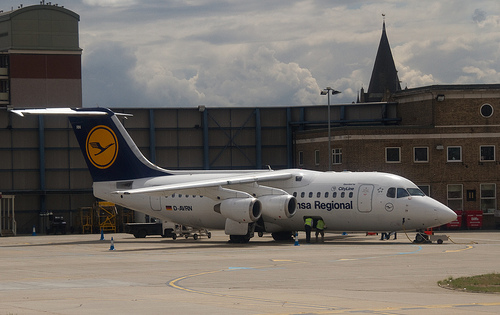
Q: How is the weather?
A: It is cloudy.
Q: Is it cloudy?
A: Yes, it is cloudy.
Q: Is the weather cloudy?
A: Yes, it is cloudy.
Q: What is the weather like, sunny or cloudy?
A: It is cloudy.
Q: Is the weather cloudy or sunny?
A: It is cloudy.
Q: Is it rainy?
A: No, it is cloudy.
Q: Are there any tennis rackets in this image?
A: No, there are no tennis rackets.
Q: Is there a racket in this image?
A: No, there are no rackets.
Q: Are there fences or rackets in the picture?
A: No, there are no rackets or fences.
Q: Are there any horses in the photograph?
A: No, there are no horses.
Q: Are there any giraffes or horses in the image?
A: No, there are no horses or giraffes.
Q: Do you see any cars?
A: No, there are no cars.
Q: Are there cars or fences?
A: No, there are no cars or fences.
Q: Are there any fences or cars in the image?
A: No, there are no cars or fences.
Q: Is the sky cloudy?
A: Yes, the sky is cloudy.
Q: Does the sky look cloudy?
A: Yes, the sky is cloudy.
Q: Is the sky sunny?
A: No, the sky is cloudy.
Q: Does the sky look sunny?
A: No, the sky is cloudy.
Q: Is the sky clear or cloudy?
A: The sky is cloudy.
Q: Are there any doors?
A: Yes, there is a door.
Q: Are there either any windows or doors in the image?
A: Yes, there is a door.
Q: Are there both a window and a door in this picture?
A: Yes, there are both a door and a window.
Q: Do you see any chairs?
A: No, there are no chairs.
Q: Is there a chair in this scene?
A: No, there are no chairs.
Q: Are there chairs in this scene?
A: No, there are no chairs.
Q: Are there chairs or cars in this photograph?
A: No, there are no chairs or cars.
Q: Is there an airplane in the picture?
A: Yes, there is an airplane.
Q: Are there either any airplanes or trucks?
A: Yes, there is an airplane.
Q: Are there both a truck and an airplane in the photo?
A: No, there is an airplane but no trucks.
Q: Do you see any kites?
A: No, there are no kites.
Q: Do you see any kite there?
A: No, there are no kites.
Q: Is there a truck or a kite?
A: No, there are no kites or trucks.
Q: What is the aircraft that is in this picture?
A: The aircraft is an airplane.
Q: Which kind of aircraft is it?
A: The aircraft is an airplane.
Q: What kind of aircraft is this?
A: This is an airplane.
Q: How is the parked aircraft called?
A: The aircraft is an airplane.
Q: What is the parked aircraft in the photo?
A: The aircraft is an airplane.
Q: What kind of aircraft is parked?
A: The aircraft is an airplane.